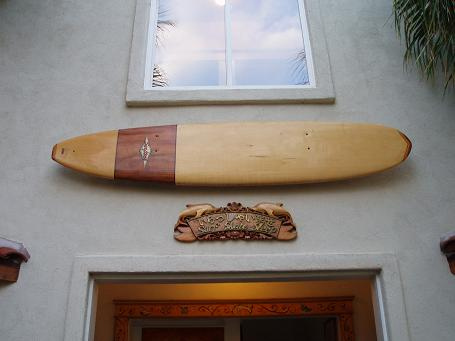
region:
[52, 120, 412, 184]
light colored wooden surfboard with dark colored stripe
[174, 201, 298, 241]
carved wooden business establishment sign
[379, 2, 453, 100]
green palm tree leaves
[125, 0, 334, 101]
reflective window with grey casing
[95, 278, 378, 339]
bronze colored wooden doorway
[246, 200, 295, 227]
tiny carved wooden dolphin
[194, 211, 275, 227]
gold colored japanese character text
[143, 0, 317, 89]
reflection of cloudy sky in window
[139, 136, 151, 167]
diamond shaped white and red surfboard logo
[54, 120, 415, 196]
black shadow of the surfboard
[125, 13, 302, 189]
the window is clear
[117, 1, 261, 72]
the window is clear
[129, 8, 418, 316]
the window is clear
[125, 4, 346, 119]
the window is clear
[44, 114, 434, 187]
Surfboard hanging on wall above door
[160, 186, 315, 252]
Wood carving above door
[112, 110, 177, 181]
Decal on the surfboard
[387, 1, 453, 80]
Palm tree leaves against wall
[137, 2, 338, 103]
Window above the surfboard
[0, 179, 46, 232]
The wall is made of cement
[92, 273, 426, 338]
Wooden doorway arch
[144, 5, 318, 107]
Reflection in the window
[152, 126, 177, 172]
Holes in the surf board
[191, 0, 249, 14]
Reflection of sun in window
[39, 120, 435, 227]
the surfing board is hanging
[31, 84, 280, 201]
the surfing board is hanging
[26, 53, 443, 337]
the surfing board is hanging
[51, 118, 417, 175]
WOODEN SURFBOARD ON WALL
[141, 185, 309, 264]
WOODEN SYMBOL OVER DOOR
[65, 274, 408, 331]
DOUBLE DOORS TO BUILDING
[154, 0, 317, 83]
WINDOW WITH REFLECTION ON GLASS PANES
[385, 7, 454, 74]
GREEN PALM TREE LEAVES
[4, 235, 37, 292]
Red balcony on white wall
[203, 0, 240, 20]
Street light reflecting in window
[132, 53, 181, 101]
Palm tree leaves reflecting in window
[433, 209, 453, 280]
Red balcony on white wall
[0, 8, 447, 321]
Side of white building